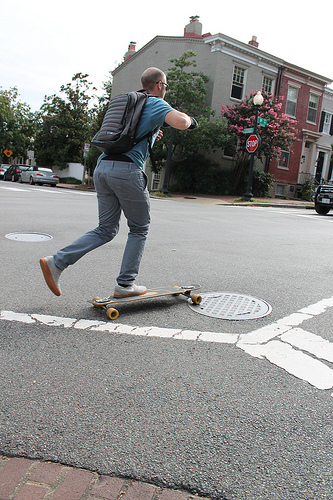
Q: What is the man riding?
A: Skateboard.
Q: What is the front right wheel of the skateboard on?
A: Manhole cover.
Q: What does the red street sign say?
A: Stop.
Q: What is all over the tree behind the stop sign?
A: Pink flowers.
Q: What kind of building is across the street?
A: Townhouses.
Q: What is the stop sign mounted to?
A: Light post.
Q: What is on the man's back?
A: Black backpack.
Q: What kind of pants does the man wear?
A: Gray slacks.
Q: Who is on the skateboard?
A: The man.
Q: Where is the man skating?
A: On the road.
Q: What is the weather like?
A: Fair.